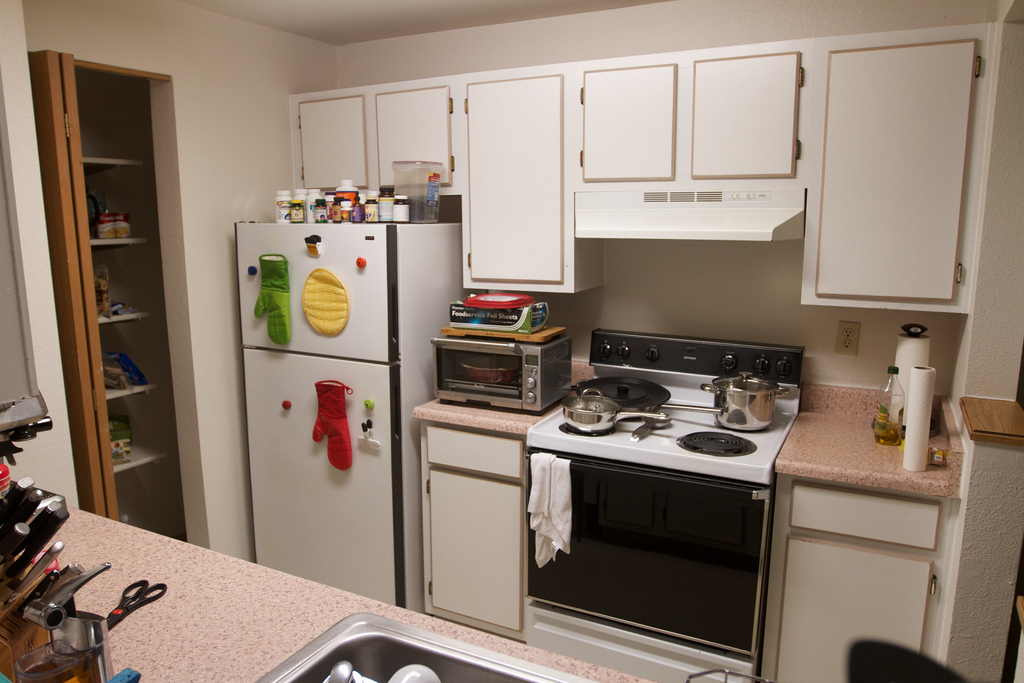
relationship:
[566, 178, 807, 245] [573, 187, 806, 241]
rangehood above rangehood